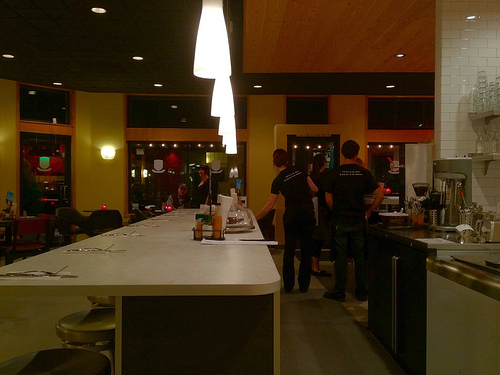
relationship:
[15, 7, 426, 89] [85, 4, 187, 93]
ceiling has on it some lights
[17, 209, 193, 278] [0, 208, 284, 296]
utensils are on counter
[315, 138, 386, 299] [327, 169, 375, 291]
bartender wears black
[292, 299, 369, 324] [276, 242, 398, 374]
shadow on floor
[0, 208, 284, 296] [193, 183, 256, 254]
counter has on it many items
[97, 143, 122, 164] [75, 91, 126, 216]
light hangs on wall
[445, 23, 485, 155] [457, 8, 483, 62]
tiles show a reflection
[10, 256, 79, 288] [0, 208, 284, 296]
silverware on counter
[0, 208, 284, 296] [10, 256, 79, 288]
counter has on it some silverware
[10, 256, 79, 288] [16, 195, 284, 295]
silverware sits on counter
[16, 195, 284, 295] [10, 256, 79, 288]
counter has on it some silverware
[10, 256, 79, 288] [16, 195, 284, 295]
silverware on counter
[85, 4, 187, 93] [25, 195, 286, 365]
lights hang over bar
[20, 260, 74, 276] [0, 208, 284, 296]
fork on counter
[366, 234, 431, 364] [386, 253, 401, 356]
cabinet has handles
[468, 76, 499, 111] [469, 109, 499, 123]
glasses are on shelf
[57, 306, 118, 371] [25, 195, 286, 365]
bar stool under bar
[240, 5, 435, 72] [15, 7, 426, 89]
paneling on ceiling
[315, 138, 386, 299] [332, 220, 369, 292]
man wears blue jeans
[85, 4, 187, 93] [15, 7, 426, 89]
lights are on ceiling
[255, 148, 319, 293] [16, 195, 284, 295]
woman are behind counter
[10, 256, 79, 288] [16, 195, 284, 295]
silverware was on counter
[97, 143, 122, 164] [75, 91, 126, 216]
light on wall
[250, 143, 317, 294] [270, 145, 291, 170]
woman has short hair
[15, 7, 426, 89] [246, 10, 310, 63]
ceiling made of wood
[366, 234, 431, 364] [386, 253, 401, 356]
cabinets have metal bars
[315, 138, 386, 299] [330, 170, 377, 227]
man shows h back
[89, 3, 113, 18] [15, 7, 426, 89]
light on ceiling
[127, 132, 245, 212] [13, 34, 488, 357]
window inside restaurant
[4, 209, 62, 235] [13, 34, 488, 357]
table in restaurant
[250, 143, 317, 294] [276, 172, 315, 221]
woman wearing black